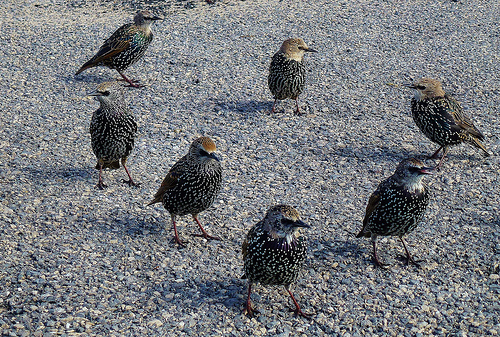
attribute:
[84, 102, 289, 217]
pavement — asphalt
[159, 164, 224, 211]
talls feathers — tail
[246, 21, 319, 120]
bird — black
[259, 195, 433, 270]
black and white — birds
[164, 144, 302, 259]
birds — standing